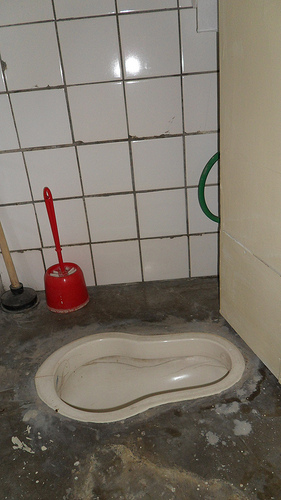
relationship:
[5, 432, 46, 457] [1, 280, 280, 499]
spots on floor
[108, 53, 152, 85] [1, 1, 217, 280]
light reflection on tiles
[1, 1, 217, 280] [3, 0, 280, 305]
tiles on wall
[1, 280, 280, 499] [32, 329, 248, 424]
floor under toilet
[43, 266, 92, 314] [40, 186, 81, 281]
container for toilet brush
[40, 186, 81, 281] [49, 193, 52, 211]
toilet brush made of plastic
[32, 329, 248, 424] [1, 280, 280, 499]
toilet in floor